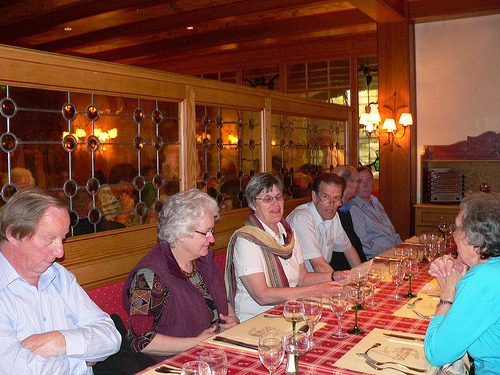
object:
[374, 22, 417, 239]
wall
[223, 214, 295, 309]
scarf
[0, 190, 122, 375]
man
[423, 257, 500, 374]
blue shirt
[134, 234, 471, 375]
dinner table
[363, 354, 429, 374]
fork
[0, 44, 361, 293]
divider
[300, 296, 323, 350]
glass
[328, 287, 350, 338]
glass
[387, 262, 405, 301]
glass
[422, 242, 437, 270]
glass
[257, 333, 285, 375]
glass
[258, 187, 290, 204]
glass woman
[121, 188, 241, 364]
glasses woman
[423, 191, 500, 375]
glasses woman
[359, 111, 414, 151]
light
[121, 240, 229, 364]
vest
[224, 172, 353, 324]
woman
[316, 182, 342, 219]
face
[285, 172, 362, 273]
man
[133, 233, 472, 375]
tablecloth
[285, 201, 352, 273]
shirt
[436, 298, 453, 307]
watch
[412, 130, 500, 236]
cabinet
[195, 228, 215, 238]
eyeglasses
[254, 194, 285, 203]
eyeglasses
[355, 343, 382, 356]
utensils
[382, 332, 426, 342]
utensils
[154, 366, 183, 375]
utensils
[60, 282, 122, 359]
arm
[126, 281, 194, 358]
arm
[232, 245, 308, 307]
arm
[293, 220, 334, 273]
arm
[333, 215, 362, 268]
arm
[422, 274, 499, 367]
arm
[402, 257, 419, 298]
wine glass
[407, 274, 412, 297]
stem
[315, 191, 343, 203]
glasses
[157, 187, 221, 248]
hair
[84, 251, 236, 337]
bench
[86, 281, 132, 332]
part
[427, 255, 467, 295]
hands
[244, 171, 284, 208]
hair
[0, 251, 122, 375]
shirt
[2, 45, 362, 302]
divider wall